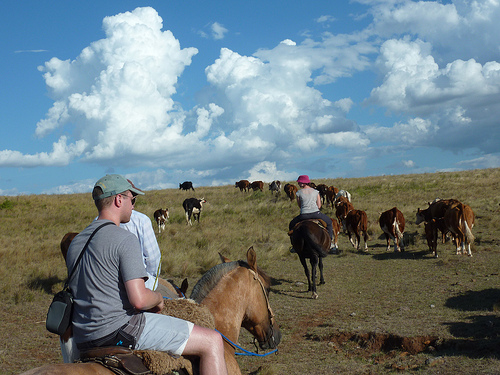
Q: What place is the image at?
A: It is at the field.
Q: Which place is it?
A: It is a field.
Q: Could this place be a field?
A: Yes, it is a field.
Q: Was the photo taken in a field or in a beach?
A: It was taken at a field.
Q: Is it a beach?
A: No, it is a field.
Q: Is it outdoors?
A: Yes, it is outdoors.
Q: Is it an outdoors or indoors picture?
A: It is outdoors.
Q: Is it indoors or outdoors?
A: It is outdoors.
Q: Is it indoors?
A: No, it is outdoors.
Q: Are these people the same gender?
A: No, they are both male and female.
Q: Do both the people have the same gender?
A: No, they are both male and female.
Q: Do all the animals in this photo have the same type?
A: No, they are horses and cows.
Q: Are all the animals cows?
A: No, there are both horses and cows.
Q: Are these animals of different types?
A: Yes, they are horses and cows.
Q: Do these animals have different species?
A: Yes, they are horses and cows.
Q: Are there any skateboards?
A: No, there are no skateboards.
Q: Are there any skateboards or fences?
A: No, there are no skateboards or fences.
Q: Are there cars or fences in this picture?
A: No, there are no fences or cars.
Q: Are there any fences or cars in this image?
A: No, there are no fences or cars.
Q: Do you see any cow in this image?
A: Yes, there is a cow.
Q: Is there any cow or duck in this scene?
A: Yes, there is a cow.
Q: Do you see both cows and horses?
A: Yes, there are both a cow and a horse.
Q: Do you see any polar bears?
A: No, there are no polar bears.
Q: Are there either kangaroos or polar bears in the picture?
A: No, there are no polar bears or kangaroos.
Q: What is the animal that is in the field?
A: The animal is a cow.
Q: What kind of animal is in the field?
A: The animal is a cow.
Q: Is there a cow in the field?
A: Yes, there is a cow in the field.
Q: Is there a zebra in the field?
A: No, there is a cow in the field.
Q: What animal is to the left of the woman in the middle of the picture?
A: The animal is a cow.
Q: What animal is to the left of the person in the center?
A: The animal is a cow.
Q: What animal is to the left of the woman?
A: The animal is a cow.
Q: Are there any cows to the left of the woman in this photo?
A: Yes, there is a cow to the left of the woman.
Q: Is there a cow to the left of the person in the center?
A: Yes, there is a cow to the left of the woman.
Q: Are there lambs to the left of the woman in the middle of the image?
A: No, there is a cow to the left of the woman.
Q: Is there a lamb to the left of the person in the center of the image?
A: No, there is a cow to the left of the woman.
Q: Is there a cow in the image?
A: Yes, there is a cow.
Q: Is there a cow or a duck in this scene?
A: Yes, there is a cow.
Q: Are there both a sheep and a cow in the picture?
A: No, there is a cow but no sheep.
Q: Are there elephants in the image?
A: No, there are no elephants.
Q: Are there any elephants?
A: No, there are no elephants.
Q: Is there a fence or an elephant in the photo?
A: No, there are no elephants or fences.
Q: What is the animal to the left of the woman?
A: The animal is a cow.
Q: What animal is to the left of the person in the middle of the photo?
A: The animal is a cow.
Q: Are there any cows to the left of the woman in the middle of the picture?
A: Yes, there is a cow to the left of the woman.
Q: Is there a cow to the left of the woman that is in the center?
A: Yes, there is a cow to the left of the woman.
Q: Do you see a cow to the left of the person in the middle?
A: Yes, there is a cow to the left of the woman.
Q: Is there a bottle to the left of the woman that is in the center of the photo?
A: No, there is a cow to the left of the woman.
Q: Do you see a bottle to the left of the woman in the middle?
A: No, there is a cow to the left of the woman.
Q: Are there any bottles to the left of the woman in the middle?
A: No, there is a cow to the left of the woman.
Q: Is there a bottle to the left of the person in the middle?
A: No, there is a cow to the left of the woman.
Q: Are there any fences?
A: No, there are no fences.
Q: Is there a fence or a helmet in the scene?
A: No, there are no fences or helmets.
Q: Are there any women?
A: Yes, there is a woman.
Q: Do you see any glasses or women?
A: Yes, there is a woman.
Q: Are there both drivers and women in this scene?
A: No, there is a woman but no drivers.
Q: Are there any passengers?
A: No, there are no passengers.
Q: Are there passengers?
A: No, there are no passengers.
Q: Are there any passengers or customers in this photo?
A: No, there are no passengers or customers.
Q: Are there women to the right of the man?
A: Yes, there is a woman to the right of the man.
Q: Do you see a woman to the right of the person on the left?
A: Yes, there is a woman to the right of the man.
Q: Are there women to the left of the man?
A: No, the woman is to the right of the man.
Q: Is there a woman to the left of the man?
A: No, the woman is to the right of the man.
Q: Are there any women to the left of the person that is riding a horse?
A: No, the woman is to the right of the man.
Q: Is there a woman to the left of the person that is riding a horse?
A: No, the woman is to the right of the man.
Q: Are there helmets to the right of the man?
A: No, there is a woman to the right of the man.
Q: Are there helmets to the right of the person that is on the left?
A: No, there is a woman to the right of the man.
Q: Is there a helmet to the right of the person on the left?
A: No, there is a woman to the right of the man.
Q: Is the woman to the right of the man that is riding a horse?
A: Yes, the woman is to the right of the man.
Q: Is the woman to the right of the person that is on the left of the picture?
A: Yes, the woman is to the right of the man.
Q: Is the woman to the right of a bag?
A: No, the woman is to the right of the man.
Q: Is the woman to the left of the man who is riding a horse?
A: No, the woman is to the right of the man.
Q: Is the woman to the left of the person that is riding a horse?
A: No, the woman is to the right of the man.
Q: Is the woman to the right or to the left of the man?
A: The woman is to the right of the man.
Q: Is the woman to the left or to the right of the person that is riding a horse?
A: The woman is to the right of the man.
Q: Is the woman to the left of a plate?
A: No, the woman is to the left of a cow.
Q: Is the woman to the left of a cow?
A: No, the woman is to the right of a cow.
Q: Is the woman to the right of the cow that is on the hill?
A: Yes, the woman is to the right of the cow.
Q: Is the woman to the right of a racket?
A: No, the woman is to the right of the cow.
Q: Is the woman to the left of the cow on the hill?
A: No, the woman is to the right of the cow.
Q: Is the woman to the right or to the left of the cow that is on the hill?
A: The woman is to the right of the cow.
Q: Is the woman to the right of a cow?
A: Yes, the woman is to the right of a cow.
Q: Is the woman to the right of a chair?
A: No, the woman is to the right of a cow.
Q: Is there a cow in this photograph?
A: Yes, there are cows.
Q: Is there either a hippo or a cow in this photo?
A: Yes, there are cows.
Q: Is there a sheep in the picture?
A: No, there is no sheep.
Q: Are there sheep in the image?
A: No, there are no sheep.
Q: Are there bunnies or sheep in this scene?
A: No, there are no sheep or bunnies.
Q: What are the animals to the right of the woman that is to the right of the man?
A: The animals are cows.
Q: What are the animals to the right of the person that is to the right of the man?
A: The animals are cows.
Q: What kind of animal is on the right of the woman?
A: The animals are cows.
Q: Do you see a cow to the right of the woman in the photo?
A: Yes, there are cows to the right of the woman.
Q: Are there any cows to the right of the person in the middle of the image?
A: Yes, there are cows to the right of the woman.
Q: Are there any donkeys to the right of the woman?
A: No, there are cows to the right of the woman.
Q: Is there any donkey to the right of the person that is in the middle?
A: No, there are cows to the right of the woman.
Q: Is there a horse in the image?
A: Yes, there is a horse.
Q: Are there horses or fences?
A: Yes, there is a horse.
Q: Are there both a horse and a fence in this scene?
A: No, there is a horse but no fences.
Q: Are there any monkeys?
A: No, there are no monkeys.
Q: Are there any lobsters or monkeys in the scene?
A: No, there are no monkeys or lobsters.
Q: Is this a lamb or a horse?
A: This is a horse.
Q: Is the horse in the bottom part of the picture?
A: Yes, the horse is in the bottom of the image.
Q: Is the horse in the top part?
A: No, the horse is in the bottom of the image.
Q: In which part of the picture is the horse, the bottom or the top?
A: The horse is in the bottom of the image.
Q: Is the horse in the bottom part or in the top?
A: The horse is in the bottom of the image.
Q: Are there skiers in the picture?
A: No, there are no skiers.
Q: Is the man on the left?
A: Yes, the man is on the left of the image.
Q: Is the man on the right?
A: No, the man is on the left of the image.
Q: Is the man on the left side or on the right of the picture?
A: The man is on the left of the image.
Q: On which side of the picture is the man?
A: The man is on the left of the image.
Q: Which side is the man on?
A: The man is on the left of the image.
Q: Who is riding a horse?
A: The man is riding a horse.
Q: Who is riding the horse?
A: The man is riding a horse.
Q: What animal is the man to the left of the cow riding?
A: The man is riding a horse.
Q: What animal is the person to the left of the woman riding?
A: The man is riding a horse.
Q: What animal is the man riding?
A: The man is riding a horse.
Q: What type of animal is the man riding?
A: The man is riding a horse.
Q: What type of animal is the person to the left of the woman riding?
A: The man is riding a horse.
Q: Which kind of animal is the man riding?
A: The man is riding a horse.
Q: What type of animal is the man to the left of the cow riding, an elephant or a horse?
A: The man is riding a horse.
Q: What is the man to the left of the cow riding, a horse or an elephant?
A: The man is riding a horse.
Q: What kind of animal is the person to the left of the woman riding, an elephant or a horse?
A: The man is riding a horse.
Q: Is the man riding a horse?
A: Yes, the man is riding a horse.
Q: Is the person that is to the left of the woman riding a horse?
A: Yes, the man is riding a horse.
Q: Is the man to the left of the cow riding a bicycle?
A: No, the man is riding a horse.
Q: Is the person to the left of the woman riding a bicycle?
A: No, the man is riding a horse.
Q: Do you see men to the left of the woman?
A: Yes, there is a man to the left of the woman.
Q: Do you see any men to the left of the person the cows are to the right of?
A: Yes, there is a man to the left of the woman.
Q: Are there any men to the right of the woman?
A: No, the man is to the left of the woman.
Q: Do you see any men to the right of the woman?
A: No, the man is to the left of the woman.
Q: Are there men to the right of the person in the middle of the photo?
A: No, the man is to the left of the woman.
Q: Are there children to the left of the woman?
A: No, there is a man to the left of the woman.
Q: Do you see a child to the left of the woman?
A: No, there is a man to the left of the woman.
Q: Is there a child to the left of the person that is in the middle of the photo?
A: No, there is a man to the left of the woman.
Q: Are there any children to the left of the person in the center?
A: No, there is a man to the left of the woman.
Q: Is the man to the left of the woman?
A: Yes, the man is to the left of the woman.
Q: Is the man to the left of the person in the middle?
A: Yes, the man is to the left of the woman.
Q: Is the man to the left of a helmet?
A: No, the man is to the left of the woman.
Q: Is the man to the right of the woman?
A: No, the man is to the left of the woman.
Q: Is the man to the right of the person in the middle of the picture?
A: No, the man is to the left of the woman.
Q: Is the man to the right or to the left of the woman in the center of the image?
A: The man is to the left of the woman.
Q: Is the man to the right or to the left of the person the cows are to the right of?
A: The man is to the left of the woman.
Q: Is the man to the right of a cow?
A: No, the man is to the left of a cow.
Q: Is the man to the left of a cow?
A: Yes, the man is to the left of a cow.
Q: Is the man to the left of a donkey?
A: No, the man is to the left of a cow.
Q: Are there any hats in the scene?
A: Yes, there is a hat.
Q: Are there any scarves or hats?
A: Yes, there is a hat.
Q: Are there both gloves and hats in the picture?
A: No, there is a hat but no gloves.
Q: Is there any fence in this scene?
A: No, there are no fences.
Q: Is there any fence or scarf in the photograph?
A: No, there are no fences or scarves.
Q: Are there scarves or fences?
A: No, there are no fences or scarves.